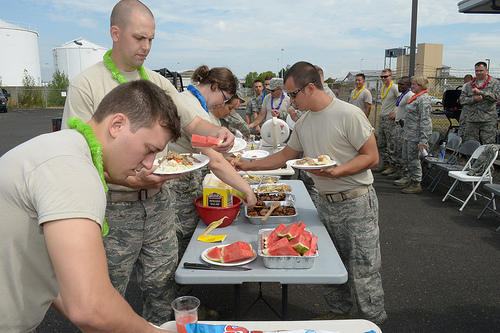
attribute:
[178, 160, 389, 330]
table — folding 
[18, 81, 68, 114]
fence —  top  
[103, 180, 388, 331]
pants —  camouflage 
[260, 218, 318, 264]
slices —  watermelon 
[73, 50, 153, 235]
leis —  green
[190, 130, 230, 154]
slice —  watermelon 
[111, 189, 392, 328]
fatigues — army 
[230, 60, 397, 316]
sunglasses — black 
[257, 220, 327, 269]
slices — watermellon 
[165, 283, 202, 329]
juice — pink 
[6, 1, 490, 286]
personnel — army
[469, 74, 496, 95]
lei — green, lime green party, yellow party , red party , blue, party, around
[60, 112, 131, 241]
flowers — green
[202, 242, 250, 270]
plate — white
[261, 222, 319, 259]
watermelon — large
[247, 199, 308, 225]
tray — baking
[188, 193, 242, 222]
bowl — red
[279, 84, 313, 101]
glasses — black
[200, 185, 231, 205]
box — small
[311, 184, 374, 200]
belt — tan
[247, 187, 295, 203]
pan — foil , watermelon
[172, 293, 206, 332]
cup — plastic , pastic , drinking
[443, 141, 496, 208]
chairs — row ,  fold out, metal, folding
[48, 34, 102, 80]
tank — white water 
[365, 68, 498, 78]
wire —  barb 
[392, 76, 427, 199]
men —  two , military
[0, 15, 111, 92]
silos — two white,  background, white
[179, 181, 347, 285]
table — folding, filled, laid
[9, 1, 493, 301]
members — military, getting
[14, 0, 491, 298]
troops — military, getting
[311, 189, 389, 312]
pants — camouflage